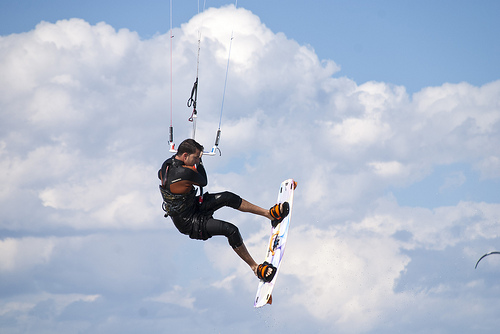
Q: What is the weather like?
A: It is cloudy.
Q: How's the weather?
A: It is cloudy.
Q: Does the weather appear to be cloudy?
A: Yes, it is cloudy.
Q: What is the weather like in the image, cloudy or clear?
A: It is cloudy.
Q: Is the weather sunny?
A: No, it is cloudy.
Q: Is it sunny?
A: No, it is cloudy.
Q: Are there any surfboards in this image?
A: Yes, there is a surfboard.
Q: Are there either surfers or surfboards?
A: Yes, there is a surfboard.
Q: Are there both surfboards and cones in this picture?
A: No, there is a surfboard but no cones.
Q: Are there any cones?
A: No, there are no cones.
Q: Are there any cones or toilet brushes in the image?
A: No, there are no cones or toilet brushes.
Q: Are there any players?
A: No, there are no players.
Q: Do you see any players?
A: No, there are no players.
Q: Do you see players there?
A: No, there are no players.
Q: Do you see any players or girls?
A: No, there are no players or girls.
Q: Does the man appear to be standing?
A: Yes, the man is standing.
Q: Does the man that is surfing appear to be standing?
A: Yes, the man is standing.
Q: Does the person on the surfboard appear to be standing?
A: Yes, the man is standing.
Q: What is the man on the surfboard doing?
A: The man is standing.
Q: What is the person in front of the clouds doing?
A: The man is standing.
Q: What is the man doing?
A: The man is standing.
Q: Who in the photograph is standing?
A: The man is standing.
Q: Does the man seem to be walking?
A: No, the man is standing.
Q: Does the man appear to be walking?
A: No, the man is standing.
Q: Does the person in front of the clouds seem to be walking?
A: No, the man is standing.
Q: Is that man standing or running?
A: The man is standing.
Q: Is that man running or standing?
A: The man is standing.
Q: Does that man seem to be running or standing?
A: The man is standing.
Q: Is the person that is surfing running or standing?
A: The man is standing.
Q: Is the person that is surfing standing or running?
A: The man is standing.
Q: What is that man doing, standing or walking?
A: The man is standing.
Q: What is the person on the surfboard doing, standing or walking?
A: The man is standing.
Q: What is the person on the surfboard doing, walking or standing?
A: The man is standing.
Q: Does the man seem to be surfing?
A: Yes, the man is surfing.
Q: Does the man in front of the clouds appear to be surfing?
A: Yes, the man is surfing.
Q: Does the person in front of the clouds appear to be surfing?
A: Yes, the man is surfing.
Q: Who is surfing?
A: The man is surfing.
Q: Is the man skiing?
A: No, the man is surfing.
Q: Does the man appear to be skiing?
A: No, the man is surfing.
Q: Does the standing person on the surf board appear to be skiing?
A: No, the man is surfing.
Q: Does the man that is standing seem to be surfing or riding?
A: The man is surfing.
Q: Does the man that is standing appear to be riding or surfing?
A: The man is surfing.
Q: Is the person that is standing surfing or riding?
A: The man is surfing.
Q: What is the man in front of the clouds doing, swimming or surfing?
A: The man is surfing.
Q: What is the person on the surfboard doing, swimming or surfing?
A: The man is surfing.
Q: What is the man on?
A: The man is on the surfboard.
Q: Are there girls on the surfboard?
A: No, there is a man on the surfboard.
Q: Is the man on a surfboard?
A: Yes, the man is on a surfboard.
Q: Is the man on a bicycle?
A: No, the man is on a surfboard.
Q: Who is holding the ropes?
A: The man is holding the ropes.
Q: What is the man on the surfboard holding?
A: The man is holding the ropes.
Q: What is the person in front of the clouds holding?
A: The man is holding the ropes.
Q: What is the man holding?
A: The man is holding the ropes.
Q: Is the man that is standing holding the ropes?
A: Yes, the man is holding the ropes.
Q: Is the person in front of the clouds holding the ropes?
A: Yes, the man is holding the ropes.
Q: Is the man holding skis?
A: No, the man is holding the ropes.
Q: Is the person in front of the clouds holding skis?
A: No, the man is holding the ropes.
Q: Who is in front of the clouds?
A: The man is in front of the clouds.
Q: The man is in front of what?
A: The man is in front of the clouds.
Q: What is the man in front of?
A: The man is in front of the clouds.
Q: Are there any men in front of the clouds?
A: Yes, there is a man in front of the clouds.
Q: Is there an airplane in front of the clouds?
A: No, there is a man in front of the clouds.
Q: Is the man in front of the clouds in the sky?
A: Yes, the man is in front of the clouds.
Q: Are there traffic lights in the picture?
A: No, there are no traffic lights.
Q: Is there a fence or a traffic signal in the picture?
A: No, there are no traffic lights or fences.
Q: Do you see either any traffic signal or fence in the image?
A: No, there are no traffic lights or fences.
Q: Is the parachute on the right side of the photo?
A: Yes, the parachute is on the right of the image.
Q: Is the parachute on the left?
A: No, the parachute is on the right of the image.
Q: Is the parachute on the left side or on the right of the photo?
A: The parachute is on the right of the image.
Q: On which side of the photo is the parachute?
A: The parachute is on the right of the image.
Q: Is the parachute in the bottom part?
A: Yes, the parachute is in the bottom of the image.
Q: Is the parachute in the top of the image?
A: No, the parachute is in the bottom of the image.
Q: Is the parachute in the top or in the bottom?
A: The parachute is in the bottom of the image.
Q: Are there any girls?
A: No, there are no girls.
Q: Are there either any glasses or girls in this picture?
A: No, there are no girls or glasses.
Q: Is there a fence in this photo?
A: No, there are no fences.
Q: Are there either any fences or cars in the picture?
A: No, there are no fences or cars.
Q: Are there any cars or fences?
A: No, there are no fences or cars.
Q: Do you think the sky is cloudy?
A: Yes, the sky is cloudy.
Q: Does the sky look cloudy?
A: Yes, the sky is cloudy.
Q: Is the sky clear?
A: No, the sky is cloudy.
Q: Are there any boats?
A: No, there are no boats.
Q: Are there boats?
A: No, there are no boats.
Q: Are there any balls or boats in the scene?
A: No, there are no boats or balls.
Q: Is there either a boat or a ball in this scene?
A: No, there are no boats or balls.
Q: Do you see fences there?
A: No, there are no fences.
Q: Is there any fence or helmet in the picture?
A: No, there are no fences or helmets.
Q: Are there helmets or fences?
A: No, there are no fences or helmets.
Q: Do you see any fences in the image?
A: No, there are no fences.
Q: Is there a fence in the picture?
A: No, there are no fences.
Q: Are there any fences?
A: No, there are no fences.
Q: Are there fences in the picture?
A: No, there are no fences.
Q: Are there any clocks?
A: No, there are no clocks.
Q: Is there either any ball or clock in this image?
A: No, there are no clocks or balls.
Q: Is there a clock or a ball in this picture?
A: No, there are no clocks or balls.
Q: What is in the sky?
A: The clouds are in the sky.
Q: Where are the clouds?
A: The clouds are in the sky.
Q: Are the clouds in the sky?
A: Yes, the clouds are in the sky.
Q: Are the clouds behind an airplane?
A: No, the clouds are behind a man.